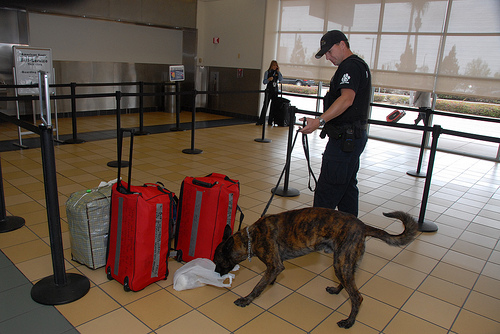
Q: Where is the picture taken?
A: In an air terminal.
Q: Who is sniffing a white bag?
A: The large dog.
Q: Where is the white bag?
A: Next to the red luggage.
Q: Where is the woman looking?
A: At the dog.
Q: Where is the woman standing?
A: Near the windows.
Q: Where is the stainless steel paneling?
A: On the walls.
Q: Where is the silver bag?
A: Behind the red luggage?.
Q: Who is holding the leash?
A: The cop.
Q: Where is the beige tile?
A: On the floor/.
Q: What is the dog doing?
A: Sniffing luggage.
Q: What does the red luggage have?
A: Handles.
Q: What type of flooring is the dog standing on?
A: Tiled flooring.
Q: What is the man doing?
A: Watching the dog.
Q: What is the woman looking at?
A: A cell phone.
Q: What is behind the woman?
A: A window.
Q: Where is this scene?
A: An airport.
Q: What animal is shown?
A: A dog.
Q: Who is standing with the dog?
A: An officer.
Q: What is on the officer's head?
A: A cap.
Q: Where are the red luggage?
A: In front of the dog.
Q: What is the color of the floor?
A: Brown.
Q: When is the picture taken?
A: Daytime.